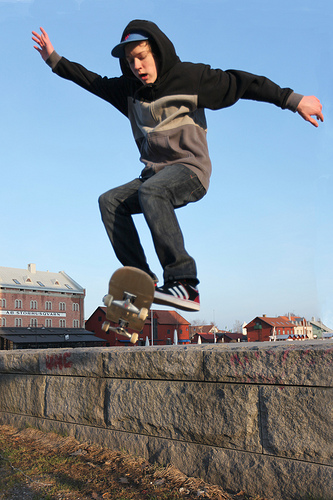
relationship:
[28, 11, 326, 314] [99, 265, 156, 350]
boy performing on skateboard